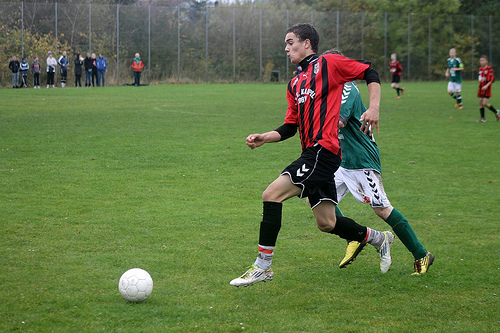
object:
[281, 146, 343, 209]
shorts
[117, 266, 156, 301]
ball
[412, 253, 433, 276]
shoes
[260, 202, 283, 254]
socks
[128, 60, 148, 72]
jackst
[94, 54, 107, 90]
people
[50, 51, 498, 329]
game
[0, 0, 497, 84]
fence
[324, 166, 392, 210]
shorts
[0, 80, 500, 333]
grass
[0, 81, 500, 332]
field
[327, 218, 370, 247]
sock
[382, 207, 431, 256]
sock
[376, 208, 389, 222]
knee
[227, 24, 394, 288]
guys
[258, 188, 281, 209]
knee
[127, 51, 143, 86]
fans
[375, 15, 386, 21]
leaves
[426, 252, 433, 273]
cleats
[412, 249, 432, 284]
foot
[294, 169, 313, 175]
white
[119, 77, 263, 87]
sidelines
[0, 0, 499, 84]
trees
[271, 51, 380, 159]
jersey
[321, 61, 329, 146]
stripes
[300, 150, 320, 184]
piping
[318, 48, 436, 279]
players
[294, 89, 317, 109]
lettering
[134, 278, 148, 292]
hexagon  shapes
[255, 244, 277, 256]
band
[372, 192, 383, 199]
arrows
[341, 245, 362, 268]
cleat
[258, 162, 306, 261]
leg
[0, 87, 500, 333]
ground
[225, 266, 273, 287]
shoes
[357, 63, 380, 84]
sleeve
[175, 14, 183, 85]
poles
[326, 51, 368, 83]
sleeve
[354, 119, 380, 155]
stripe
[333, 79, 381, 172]
shirt